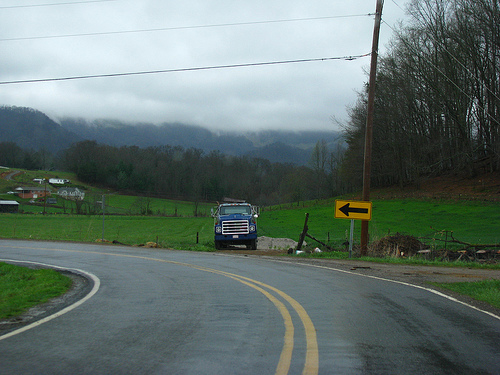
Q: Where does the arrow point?
A: Left.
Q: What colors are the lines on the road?
A: Yellow and white.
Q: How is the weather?
A: Rainy.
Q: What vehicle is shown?
A: Truck.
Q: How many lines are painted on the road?
A: 4.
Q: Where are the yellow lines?
A: Middle of road.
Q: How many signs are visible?
A: 1.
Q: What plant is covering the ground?
A: Grass.